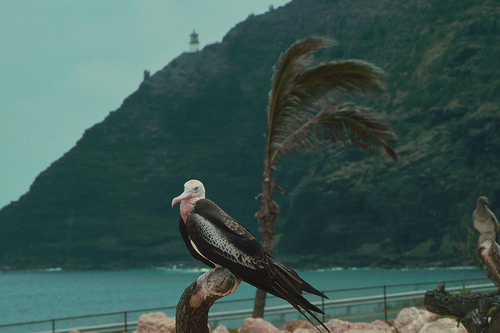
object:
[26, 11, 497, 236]
cliff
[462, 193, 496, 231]
head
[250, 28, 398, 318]
palm tree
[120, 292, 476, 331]
rocks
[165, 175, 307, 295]
bird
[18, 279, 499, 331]
rail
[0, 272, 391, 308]
water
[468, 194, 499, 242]
bird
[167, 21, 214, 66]
lighthouse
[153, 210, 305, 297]
feathers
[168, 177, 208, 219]
head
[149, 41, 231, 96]
bluff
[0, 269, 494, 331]
water body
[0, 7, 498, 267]
vegetation